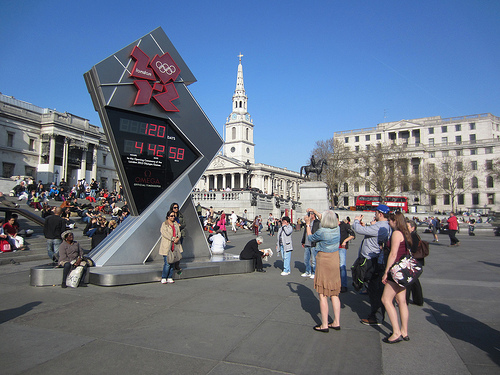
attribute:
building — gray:
[330, 116, 499, 221]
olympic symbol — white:
[155, 60, 177, 76]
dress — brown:
[316, 245, 341, 297]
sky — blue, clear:
[303, 25, 468, 102]